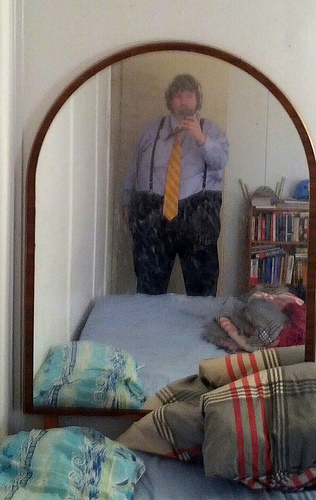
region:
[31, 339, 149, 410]
THIS A BLUE PILLOW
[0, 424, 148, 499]
THIS IS A REFLECTION OF A PILLOW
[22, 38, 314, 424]
THIS A BROWN MIRROR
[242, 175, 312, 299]
THIS IS A BOOKSHELF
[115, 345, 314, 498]
THIS A PLAIDED BLANKET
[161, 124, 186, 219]
THIS IS A MAN'S TIE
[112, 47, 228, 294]
THIS IS A DOOR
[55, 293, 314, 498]
THIS IS A BED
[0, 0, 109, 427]
THIS IS THE LEFT SIDE OF THE WALL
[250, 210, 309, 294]
THESE ARE BOOKS ON THE SHELF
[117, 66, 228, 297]
person in a mirror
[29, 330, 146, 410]
reflection of a pillow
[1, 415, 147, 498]
pillow on the bed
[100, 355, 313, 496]
blanket on the bed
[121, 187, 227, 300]
pair of black pants in mirror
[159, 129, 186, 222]
yellow tie in mirror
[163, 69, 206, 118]
head of a person in mirror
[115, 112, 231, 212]
blue dress shirt in mirror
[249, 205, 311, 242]
row of books in mirror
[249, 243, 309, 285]
row of books in mirror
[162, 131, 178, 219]
The tie the man is wearing.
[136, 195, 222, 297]
The pants the man is wearing.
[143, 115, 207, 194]
The suspenders attached to the man's pants.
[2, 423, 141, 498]
The pillow on the left.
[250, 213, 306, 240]
The books on the top shelf.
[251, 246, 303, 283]
The books on the second shelf.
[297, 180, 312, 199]
The blue helmet on the shelf.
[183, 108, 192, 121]
The phone in the man's hand.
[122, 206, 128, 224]
The left hand of the man.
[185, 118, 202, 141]
The right hand of the man.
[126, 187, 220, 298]
Man wearing pants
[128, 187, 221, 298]
Man is wearing pants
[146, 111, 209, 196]
Man wearing suspenders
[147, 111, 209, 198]
Man is wearing suspenders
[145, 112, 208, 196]
Man wearing black suspenders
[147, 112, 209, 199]
Man is wearing black suspenders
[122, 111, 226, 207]
Man wearing a blue shirt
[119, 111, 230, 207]
Man is wearing a blue shirt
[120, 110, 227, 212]
Man wearing a long sleeved blue shirt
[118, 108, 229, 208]
Man is wearing a long sleeved blue shirt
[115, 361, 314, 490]
A multi tone gray comforter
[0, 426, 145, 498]
A blue and white ocean like pillowcase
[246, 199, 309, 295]
The reflection of a bookcase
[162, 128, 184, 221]
A two tone gold tie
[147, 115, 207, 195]
A pair of black suspenders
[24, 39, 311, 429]
A wooden framed mirror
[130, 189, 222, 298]
Very large black pants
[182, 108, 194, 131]
A grey cell phone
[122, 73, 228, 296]
A large man taking a selfie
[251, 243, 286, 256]
A pile of books